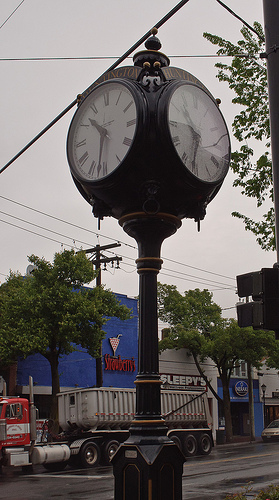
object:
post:
[109, 214, 186, 500]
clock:
[66, 80, 140, 188]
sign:
[160, 369, 209, 388]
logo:
[105, 351, 138, 373]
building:
[16, 264, 140, 395]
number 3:
[127, 118, 137, 128]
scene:
[0, 0, 279, 498]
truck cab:
[1, 391, 34, 474]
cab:
[0, 396, 29, 448]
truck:
[0, 369, 214, 471]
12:
[101, 88, 111, 106]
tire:
[182, 431, 198, 460]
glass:
[108, 336, 120, 357]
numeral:
[76, 139, 88, 154]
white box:
[56, 379, 212, 431]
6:
[100, 157, 109, 179]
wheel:
[79, 439, 102, 473]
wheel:
[168, 435, 185, 465]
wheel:
[197, 431, 219, 459]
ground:
[0, 439, 279, 498]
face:
[66, 80, 138, 181]